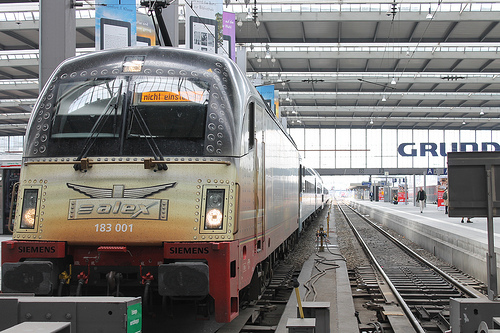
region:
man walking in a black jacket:
[415, 187, 426, 213]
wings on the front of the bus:
[65, 180, 175, 195]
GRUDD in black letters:
[398, 139, 496, 159]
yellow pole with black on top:
[291, 277, 303, 317]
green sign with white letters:
[126, 302, 142, 332]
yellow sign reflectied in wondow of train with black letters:
[141, 91, 203, 103]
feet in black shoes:
[461, 217, 473, 224]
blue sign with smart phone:
[93, 0, 138, 50]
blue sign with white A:
[426, 167, 433, 174]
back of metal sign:
[446, 149, 498, 219]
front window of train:
[45, 65, 211, 144]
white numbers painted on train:
[87, 215, 137, 239]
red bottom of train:
[2, 238, 270, 319]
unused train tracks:
[338, 195, 491, 327]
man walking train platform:
[407, 183, 432, 213]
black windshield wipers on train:
[79, 89, 171, 154]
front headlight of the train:
[17, 181, 225, 234]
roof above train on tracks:
[2, 8, 498, 133]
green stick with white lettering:
[125, 303, 145, 332]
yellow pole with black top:
[282, 273, 317, 318]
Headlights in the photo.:
[205, 209, 222, 230]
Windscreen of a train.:
[145, 82, 201, 137]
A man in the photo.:
[410, 184, 430, 216]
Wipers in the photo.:
[115, 96, 164, 166]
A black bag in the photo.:
[441, 190, 446, 201]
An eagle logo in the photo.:
[68, 180, 176, 200]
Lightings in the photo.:
[307, 44, 373, 53]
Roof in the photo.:
[345, 6, 460, 116]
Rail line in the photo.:
[377, 244, 439, 298]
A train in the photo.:
[19, 52, 250, 302]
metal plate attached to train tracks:
[438, 148, 498, 331]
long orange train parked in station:
[7, 28, 339, 328]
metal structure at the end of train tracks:
[1, 279, 158, 331]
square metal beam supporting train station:
[31, 0, 84, 318]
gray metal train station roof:
[0, 0, 499, 133]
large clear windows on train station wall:
[3, 117, 498, 177]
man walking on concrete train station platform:
[413, 184, 430, 215]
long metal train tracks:
[331, 190, 497, 332]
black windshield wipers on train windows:
[69, 73, 169, 176]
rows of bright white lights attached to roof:
[0, 2, 498, 132]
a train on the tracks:
[3, 43, 331, 320]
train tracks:
[332, 195, 490, 332]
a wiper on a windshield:
[73, 80, 122, 171]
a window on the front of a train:
[125, 80, 210, 141]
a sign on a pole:
[446, 152, 498, 221]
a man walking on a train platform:
[415, 186, 427, 214]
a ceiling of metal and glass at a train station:
[0, 2, 497, 130]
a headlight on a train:
[204, 209, 223, 229]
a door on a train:
[255, 103, 268, 254]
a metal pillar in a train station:
[33, 0, 78, 95]